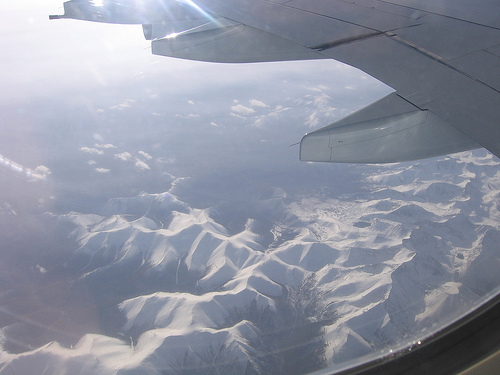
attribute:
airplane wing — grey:
[59, 0, 495, 167]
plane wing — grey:
[59, 7, 496, 223]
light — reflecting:
[87, 1, 226, 33]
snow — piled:
[1, 147, 499, 374]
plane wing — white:
[55, 6, 499, 156]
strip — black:
[339, 300, 499, 373]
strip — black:
[415, 319, 499, 360]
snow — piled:
[46, 195, 310, 367]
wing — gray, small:
[50, 5, 497, 167]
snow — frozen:
[2, 56, 489, 353]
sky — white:
[1, 4, 484, 372]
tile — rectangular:
[316, 31, 485, 158]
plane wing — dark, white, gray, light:
[43, 0, 484, 155]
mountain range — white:
[4, 145, 484, 373]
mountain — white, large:
[74, 210, 309, 372]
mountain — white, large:
[262, 207, 454, 363]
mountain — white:
[0, 204, 299, 374]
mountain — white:
[172, 166, 448, 366]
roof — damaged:
[302, 0, 448, 51]